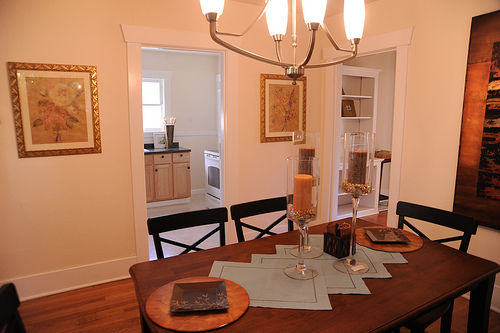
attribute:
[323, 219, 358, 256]
basket — brown , little 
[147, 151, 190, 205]
cabinets — black, brown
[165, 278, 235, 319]
square plate — floral design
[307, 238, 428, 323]
counter — black 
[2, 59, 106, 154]
painting — gold framed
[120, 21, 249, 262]
door frame — wooden, framed, white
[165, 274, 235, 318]
mat — round, wooden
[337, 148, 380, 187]
candle — brown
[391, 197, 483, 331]
dining chair — wooden, black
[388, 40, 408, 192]
frame — white , thick 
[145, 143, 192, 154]
counter — wooden, black top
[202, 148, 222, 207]
oven — black, white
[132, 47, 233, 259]
door — wooden 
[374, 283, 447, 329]
table — brown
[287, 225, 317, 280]
glass stem — glass 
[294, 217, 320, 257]
glass stem — glass 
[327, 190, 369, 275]
glass stem — glass 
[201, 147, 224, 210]
oven — white 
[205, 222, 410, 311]
placemats — brown, blue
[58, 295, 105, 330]
floor — brown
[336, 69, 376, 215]
bookcase — white 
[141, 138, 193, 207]
counter — kitchen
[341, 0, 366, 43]
lamp — four lamp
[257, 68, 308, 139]
artwork — gold, framed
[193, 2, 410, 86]
light — ceiling, brown colored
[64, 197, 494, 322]
table — wood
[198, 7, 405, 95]
lamp — chandelier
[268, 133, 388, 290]
candle holders — glass, clear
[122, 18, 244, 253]
door frame — white